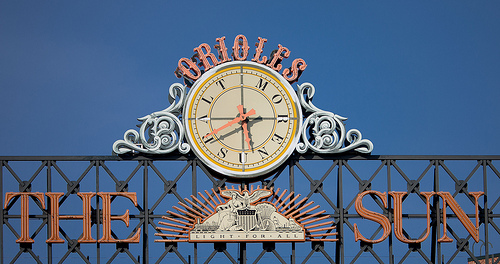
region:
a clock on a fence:
[112, 20, 457, 262]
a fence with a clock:
[114, 15, 435, 258]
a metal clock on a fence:
[134, 33, 389, 253]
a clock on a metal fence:
[110, 12, 402, 245]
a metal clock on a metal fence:
[111, 17, 474, 231]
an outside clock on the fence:
[110, 13, 386, 258]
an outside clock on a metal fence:
[119, 26, 311, 262]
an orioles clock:
[100, 26, 372, 260]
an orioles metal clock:
[125, 15, 421, 261]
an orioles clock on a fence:
[98, 16, 383, 248]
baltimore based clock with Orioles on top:
[115, 35, 372, 262]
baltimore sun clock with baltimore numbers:
[94, 46, 411, 193]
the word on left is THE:
[6, 177, 153, 262]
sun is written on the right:
[351, 180, 487, 248]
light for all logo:
[154, 175, 342, 254]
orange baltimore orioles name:
[175, 28, 319, 79]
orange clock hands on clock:
[209, 112, 262, 148]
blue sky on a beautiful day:
[24, 8, 116, 103]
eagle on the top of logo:
[216, 185, 277, 206]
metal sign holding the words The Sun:
[388, 140, 479, 175]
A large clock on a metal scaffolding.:
[95, 29, 381, 261]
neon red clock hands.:
[201, 94, 261, 159]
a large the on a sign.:
[0, 174, 156, 259]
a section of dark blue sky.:
[389, 32, 473, 76]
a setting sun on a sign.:
[139, 166, 361, 262]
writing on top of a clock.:
[164, 8, 331, 88]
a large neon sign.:
[101, 31, 395, 253]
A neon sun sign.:
[331, 162, 486, 262]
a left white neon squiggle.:
[100, 62, 197, 162]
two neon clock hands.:
[197, 88, 271, 162]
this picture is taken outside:
[27, 30, 407, 248]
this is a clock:
[159, 61, 310, 176]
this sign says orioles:
[162, 40, 290, 85]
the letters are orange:
[180, 29, 297, 73]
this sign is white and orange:
[210, 196, 295, 261]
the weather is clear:
[63, 25, 444, 213]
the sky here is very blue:
[37, 21, 171, 118]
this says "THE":
[11, 173, 157, 253]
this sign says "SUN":
[355, 182, 483, 257]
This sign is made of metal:
[108, 58, 343, 235]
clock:
[165, 55, 298, 170]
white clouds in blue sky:
[24, 18, 87, 73]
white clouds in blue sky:
[58, 15, 140, 111]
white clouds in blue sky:
[45, 98, 92, 137]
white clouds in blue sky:
[121, 23, 158, 58]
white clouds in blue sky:
[323, 30, 355, 65]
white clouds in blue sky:
[352, 32, 388, 88]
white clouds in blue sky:
[371, 65, 431, 135]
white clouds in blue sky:
[396, 3, 432, 71]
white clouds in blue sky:
[405, 69, 451, 133]